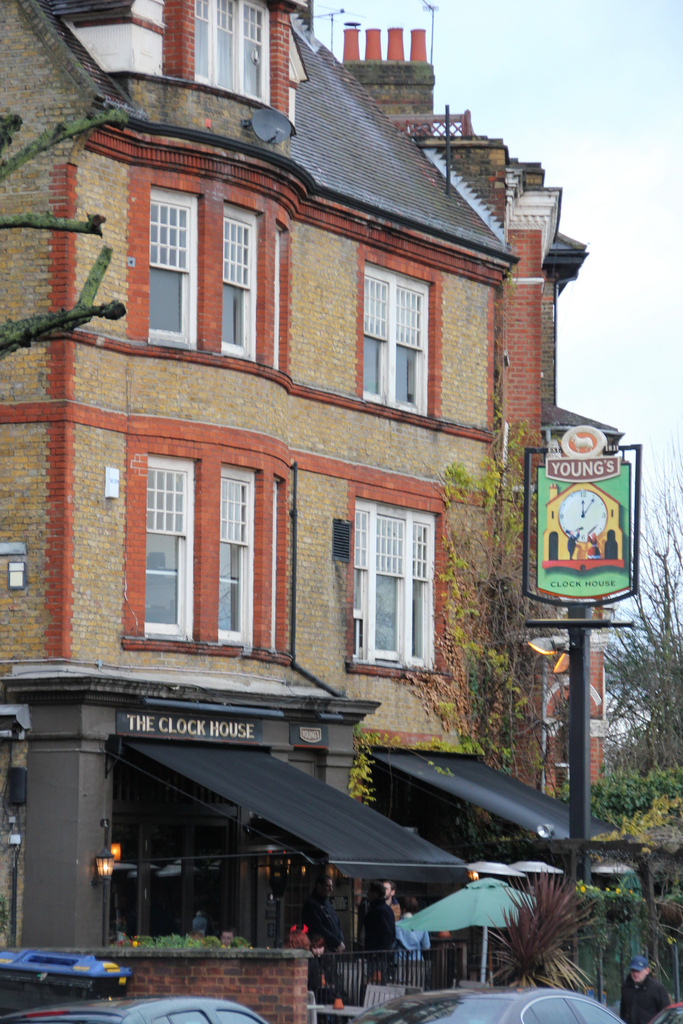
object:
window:
[220, 465, 250, 643]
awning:
[359, 753, 622, 840]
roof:
[283, 24, 508, 260]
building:
[0, 0, 583, 1016]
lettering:
[127, 714, 254, 738]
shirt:
[617, 981, 666, 1020]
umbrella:
[394, 877, 540, 949]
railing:
[309, 925, 344, 988]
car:
[415, 985, 631, 1021]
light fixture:
[94, 846, 116, 882]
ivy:
[348, 424, 516, 801]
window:
[147, 451, 193, 637]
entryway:
[25, 681, 378, 976]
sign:
[537, 455, 633, 590]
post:
[568, 624, 586, 835]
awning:
[109, 748, 469, 883]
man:
[619, 950, 670, 1021]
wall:
[6, 944, 315, 1023]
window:
[218, 197, 262, 359]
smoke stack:
[410, 32, 428, 64]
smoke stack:
[365, 30, 380, 58]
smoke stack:
[345, 32, 358, 57]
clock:
[558, 488, 607, 538]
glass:
[216, 540, 243, 635]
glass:
[146, 532, 178, 573]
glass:
[146, 573, 178, 623]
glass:
[220, 476, 246, 545]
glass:
[377, 514, 405, 577]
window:
[150, 187, 191, 341]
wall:
[70, 151, 497, 731]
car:
[0, 952, 130, 1021]